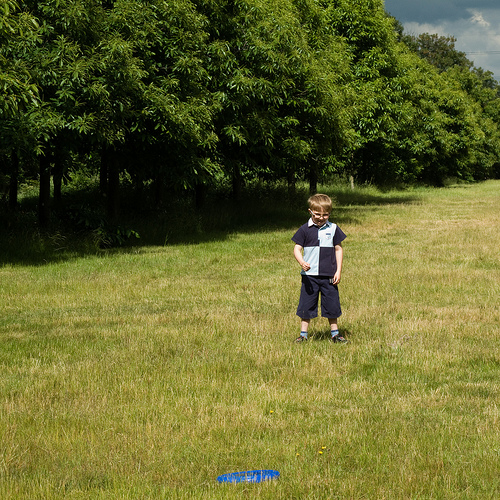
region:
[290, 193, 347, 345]
A small brown haired boy in glasses.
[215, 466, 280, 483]
A blue frisbee in the grass.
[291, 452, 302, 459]
Yellow flower closest to the frisbee.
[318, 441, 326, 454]
Two yellow flowers side by side close to the frisbee.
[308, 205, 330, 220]
Glasses on the face of a young boy.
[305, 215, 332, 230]
White collar on a boys shirt.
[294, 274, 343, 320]
Black shorts on a boy's legs.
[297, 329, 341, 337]
Blue socks on a boy.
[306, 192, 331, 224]
A brown haired boy's head.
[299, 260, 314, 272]
Right hand of a small boy.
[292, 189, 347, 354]
boy with glasses standing in the grass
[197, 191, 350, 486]
little boy playing with blue frisbee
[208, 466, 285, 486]
blue plastic frisbee on the grass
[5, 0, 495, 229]
row of healthy looking trees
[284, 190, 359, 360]
little boy standing on the grass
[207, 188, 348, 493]
boy playing with a frisbee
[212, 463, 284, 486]
blue plastic frisbee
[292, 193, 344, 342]
little boy wearing glasses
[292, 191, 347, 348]
little boy in blue shorts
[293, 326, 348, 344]
boy wearing blue socks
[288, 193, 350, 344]
Child standing on the grass field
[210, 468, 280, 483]
Blue frisbee on the ground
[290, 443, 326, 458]
Small yellow near the frisbee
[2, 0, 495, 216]
Trees behind the child in the field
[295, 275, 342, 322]
Black shorts worn by child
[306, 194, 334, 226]
Head of the child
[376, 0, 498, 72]
Blue sky in the back ground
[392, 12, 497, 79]
White cloud in the sky in the background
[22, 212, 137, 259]
Green plant near the trees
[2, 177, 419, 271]
Shadow of the trees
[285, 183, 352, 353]
the boy in the field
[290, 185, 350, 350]
the boy standing in the grass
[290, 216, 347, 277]
the blue and white tee shirt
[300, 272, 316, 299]
the shadow on the legs of the boy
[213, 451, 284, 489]
the blue colored frisbee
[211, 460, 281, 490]
the frisbee in the grass field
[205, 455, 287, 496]
the blue frisbee laying on the gorund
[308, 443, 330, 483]
the yellow color on the weeds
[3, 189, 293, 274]
the shadow under the trees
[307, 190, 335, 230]
the glasses on the boys face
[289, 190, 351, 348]
Young boy with glasses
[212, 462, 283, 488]
Blue circular frisbee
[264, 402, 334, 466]
Four yellow dandelions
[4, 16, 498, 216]
Group of green trees in forest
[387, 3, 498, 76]
Dark blue sky filled with clouds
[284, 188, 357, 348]
Boy wearing blue and black checkered shirt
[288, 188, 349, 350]
Boy wearing blue shoes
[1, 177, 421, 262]
Dark shadows on the ground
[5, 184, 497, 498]
Boy standing in a field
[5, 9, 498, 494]
Field bordered by a line of trees